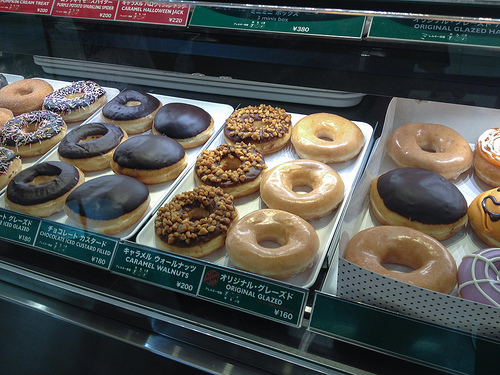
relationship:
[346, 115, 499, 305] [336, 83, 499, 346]
donuts are in box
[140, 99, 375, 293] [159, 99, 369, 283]
tray has donuts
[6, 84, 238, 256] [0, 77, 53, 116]
tray has donut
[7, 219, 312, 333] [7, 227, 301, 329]
sign has prices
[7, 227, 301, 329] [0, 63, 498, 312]
prices are for doughnuts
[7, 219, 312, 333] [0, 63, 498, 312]
sign for doughnuts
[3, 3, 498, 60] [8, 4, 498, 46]
sign has prices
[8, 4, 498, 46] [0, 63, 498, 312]
prices are for doughnuts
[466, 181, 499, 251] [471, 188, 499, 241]
doughnut has frosting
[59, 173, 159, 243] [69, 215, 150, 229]
doughnut has creme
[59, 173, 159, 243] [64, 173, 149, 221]
doughnut has frosting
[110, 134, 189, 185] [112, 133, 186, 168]
donut has frosting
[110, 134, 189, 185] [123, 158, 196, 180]
donut has creme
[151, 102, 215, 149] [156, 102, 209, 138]
donuts has frosting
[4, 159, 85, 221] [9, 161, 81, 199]
doughnut has frosting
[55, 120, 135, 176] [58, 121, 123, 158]
doughnut has frosting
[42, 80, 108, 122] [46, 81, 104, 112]
doughnut has frosting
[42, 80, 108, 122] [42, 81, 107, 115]
doughnut has sprinkles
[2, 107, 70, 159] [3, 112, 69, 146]
doughnut has frosting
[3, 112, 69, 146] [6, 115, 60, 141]
frosting has sprinkles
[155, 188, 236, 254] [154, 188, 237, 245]
doughnut has frosting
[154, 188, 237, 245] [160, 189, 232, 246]
frosting has nuts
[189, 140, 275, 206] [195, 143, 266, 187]
doughnut has frosting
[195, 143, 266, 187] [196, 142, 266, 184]
frosting has nuts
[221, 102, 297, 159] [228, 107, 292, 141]
doughnut has frosting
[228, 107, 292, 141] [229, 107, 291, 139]
frosting has nuts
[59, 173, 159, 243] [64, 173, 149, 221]
doughnut has icing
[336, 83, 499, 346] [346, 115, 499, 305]
box for donuts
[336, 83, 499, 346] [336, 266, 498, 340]
box has design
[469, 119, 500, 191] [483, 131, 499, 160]
donut has caramel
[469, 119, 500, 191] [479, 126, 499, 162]
donut has walnuts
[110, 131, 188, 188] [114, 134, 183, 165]
donut has icing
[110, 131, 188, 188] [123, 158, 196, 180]
donut has custard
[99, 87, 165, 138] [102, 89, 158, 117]
donut has glaze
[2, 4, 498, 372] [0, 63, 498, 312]
case for donuts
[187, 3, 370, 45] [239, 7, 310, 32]
placard has title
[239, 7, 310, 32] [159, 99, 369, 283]
title describes donuts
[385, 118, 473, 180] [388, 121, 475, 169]
donuts has glaze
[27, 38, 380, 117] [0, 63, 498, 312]
tray for donuts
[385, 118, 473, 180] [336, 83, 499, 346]
donuts in box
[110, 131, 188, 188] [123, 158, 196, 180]
donut has filling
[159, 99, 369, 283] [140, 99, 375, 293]
donuts are on platter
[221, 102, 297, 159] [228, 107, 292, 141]
donut has icing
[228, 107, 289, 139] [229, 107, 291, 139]
icing has peanuts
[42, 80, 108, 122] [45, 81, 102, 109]
doughnut has icing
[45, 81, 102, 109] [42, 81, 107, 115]
icing has sprinkles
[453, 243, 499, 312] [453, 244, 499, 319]
donut has frosting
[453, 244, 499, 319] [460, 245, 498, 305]
frosting has design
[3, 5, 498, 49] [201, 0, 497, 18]
shelf for donuts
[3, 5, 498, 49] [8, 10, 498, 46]
shelf has front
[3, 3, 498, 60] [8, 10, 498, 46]
text on front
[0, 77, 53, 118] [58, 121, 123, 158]
donut has no frosting